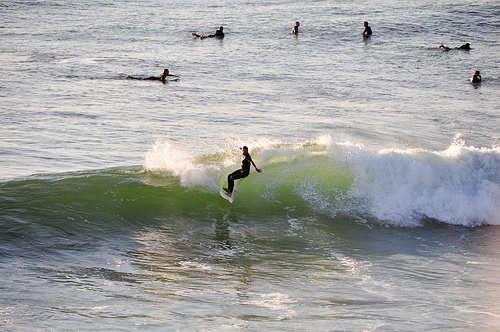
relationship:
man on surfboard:
[224, 145, 263, 195] [219, 179, 234, 208]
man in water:
[224, 145, 263, 195] [0, 0, 499, 330]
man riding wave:
[224, 145, 263, 195] [341, 141, 495, 227]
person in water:
[119, 69, 187, 85] [0, 0, 499, 330]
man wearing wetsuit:
[224, 145, 263, 195] [226, 158, 254, 192]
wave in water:
[341, 141, 495, 227] [0, 0, 499, 330]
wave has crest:
[341, 141, 495, 227] [336, 133, 500, 157]